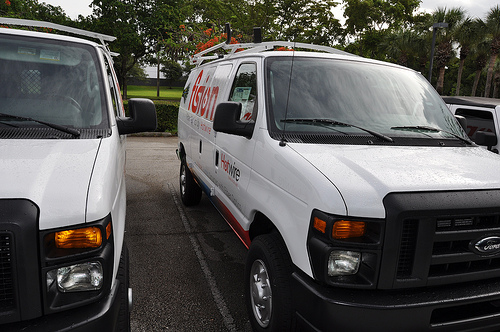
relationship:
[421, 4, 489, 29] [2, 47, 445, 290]
shower passed by trucks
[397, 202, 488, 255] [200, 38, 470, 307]
grill of truck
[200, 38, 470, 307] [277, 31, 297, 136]
truck has antenna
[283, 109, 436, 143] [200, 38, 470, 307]
windshield wipers on truck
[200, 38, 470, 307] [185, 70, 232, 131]
truck has writing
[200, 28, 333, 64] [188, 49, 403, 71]
rack on roof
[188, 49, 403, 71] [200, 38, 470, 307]
roof of truck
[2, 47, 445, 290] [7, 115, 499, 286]
trucks in parking lot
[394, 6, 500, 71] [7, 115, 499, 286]
trees in back of parking lot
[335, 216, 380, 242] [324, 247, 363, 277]
light above headlight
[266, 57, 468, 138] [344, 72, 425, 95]
window reflecting light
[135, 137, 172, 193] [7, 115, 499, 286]
blacktop of parking lot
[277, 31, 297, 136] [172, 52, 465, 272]
antenna of van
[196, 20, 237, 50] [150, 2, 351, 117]
flowers in tree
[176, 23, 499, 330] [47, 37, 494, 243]
truck in lot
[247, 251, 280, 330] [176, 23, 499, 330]
wheel of truck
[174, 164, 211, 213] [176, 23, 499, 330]
wheel of truck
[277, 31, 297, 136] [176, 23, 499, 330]
antenna on truck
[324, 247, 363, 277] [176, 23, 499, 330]
headlight of truck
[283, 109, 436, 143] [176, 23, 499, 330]
windshield wipers on truck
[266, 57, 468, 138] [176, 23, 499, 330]
window on truck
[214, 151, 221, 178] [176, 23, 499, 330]
door handle on truck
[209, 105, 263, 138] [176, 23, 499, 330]
mirror on truck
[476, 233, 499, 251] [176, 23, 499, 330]
logo on truck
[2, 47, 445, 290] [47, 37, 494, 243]
trucks in lot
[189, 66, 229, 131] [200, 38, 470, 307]
lettering on truck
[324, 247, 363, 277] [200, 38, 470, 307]
headlight of truck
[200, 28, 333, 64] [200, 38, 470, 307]
rack on truck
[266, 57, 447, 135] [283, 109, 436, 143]
window has windshield wipers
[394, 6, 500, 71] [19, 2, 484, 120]
trees in background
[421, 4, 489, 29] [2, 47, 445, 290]
shower wet trucks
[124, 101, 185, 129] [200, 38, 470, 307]
hedges behind truck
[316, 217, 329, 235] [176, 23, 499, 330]
turn signal of truck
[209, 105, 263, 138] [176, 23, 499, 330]
mirror of truck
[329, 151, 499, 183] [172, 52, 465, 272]
hood of van